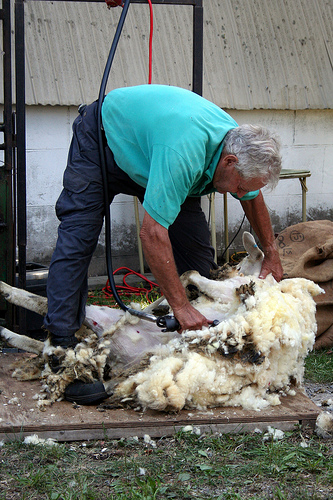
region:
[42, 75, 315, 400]
A man shearing a sheep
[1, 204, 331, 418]
A sheep being shorn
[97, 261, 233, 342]
Clippers for shearing sheep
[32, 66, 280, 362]
The man has on a green shirt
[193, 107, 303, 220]
The man has gray hair.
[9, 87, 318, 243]
The building is made of cinder blocks.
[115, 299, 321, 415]
The wool is rolling off the sheep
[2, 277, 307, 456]
The sheep is on a wooden platform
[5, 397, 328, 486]
Grass all around the platform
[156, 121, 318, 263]
A folding card table behind the man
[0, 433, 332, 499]
Green grass in front of the wooden platform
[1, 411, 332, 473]
Fur that has fallen on the ground in front of the wooden platform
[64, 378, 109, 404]
Tip of the black boot on the man's right leg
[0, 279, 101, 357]
Back legs of the animal pointing straight out to the left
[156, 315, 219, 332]
Black device the man is using to shear the animal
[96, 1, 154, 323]
Long black cord connecting the shearer to the power supply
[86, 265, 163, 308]
Red cord laying on the ground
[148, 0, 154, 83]
Red cord hanging in the background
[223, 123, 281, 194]
Man's gray hair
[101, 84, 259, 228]
Man's aqua blue shirt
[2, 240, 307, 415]
sheep being sheared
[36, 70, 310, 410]
man shearing sheep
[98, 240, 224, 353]
black electric clippers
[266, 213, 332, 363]
brown burlap bag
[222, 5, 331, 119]
gray metal roof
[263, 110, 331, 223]
cement block building painted white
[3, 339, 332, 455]
wooden platform to lay sheep on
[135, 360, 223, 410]
sheeps wool that has been cut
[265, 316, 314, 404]
sheeps wool that has been cut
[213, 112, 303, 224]
man with gray hair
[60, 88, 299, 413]
man shearing sheep wool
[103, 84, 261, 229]
green short sleeved shirt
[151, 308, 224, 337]
clipper shaving wool from sheep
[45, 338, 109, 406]
black boot covered in wool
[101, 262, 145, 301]
red power cord on ground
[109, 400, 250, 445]
wood platform on ground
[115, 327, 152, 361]
sheep body with no wool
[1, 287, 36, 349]
sheep legs in the air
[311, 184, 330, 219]
worn paint on wall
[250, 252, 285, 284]
hand holding sheep neck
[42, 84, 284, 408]
a man is shaving sheep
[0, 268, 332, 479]
the fur look yellow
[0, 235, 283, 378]
the sheep is white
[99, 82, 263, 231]
the man have on green shirt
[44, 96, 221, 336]
the man have on blue pants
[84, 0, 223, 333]
blue shaver in his hand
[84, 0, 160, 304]
a red water hose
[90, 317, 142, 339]
there are two red spots on sheep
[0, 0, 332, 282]
water pump house in the black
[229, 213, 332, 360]
there are a brown cloth on the side